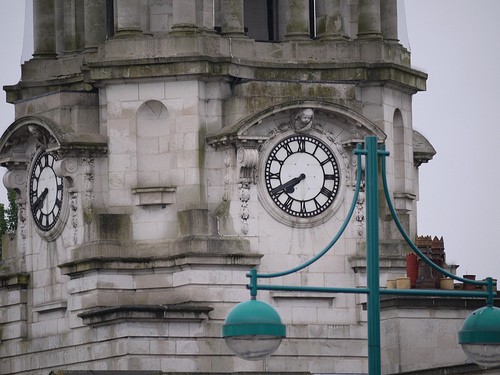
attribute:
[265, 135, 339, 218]
clock — 8:40, white, round, black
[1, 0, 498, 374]
building — stone, dirty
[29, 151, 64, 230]
clock — round, white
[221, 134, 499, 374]
light fixture — off, green, blue, steel, metal, long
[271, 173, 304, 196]
hands — black, together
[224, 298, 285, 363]
light — round, green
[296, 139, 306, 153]
number — roman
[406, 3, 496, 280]
sky — cloudy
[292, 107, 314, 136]
angel — sculpture, carved, statue